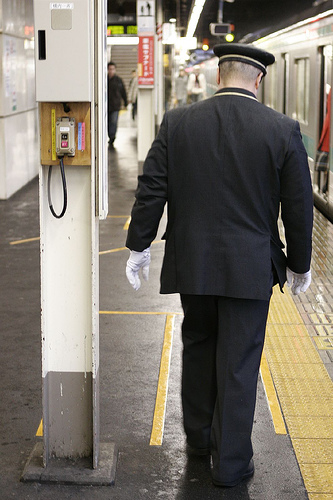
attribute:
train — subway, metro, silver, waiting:
[187, 5, 332, 223]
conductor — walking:
[124, 43, 315, 486]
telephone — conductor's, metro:
[45, 118, 85, 222]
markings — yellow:
[6, 208, 293, 450]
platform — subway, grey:
[0, 112, 332, 491]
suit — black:
[114, 88, 332, 491]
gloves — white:
[124, 248, 310, 293]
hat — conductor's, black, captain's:
[209, 40, 275, 78]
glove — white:
[122, 247, 153, 292]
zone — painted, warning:
[11, 206, 332, 486]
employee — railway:
[115, 42, 322, 490]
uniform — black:
[121, 39, 319, 490]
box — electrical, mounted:
[39, 95, 92, 170]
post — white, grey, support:
[15, 2, 123, 489]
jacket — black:
[113, 88, 317, 301]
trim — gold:
[210, 90, 261, 106]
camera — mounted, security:
[208, 1, 236, 40]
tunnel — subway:
[5, 4, 330, 498]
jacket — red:
[315, 92, 333, 156]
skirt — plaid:
[313, 153, 332, 173]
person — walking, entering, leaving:
[108, 58, 131, 146]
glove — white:
[286, 269, 313, 297]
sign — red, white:
[135, 31, 162, 93]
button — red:
[61, 141, 71, 148]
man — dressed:
[120, 34, 330, 488]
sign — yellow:
[109, 23, 140, 36]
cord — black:
[47, 154, 68, 219]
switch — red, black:
[59, 131, 69, 151]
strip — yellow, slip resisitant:
[262, 280, 333, 498]